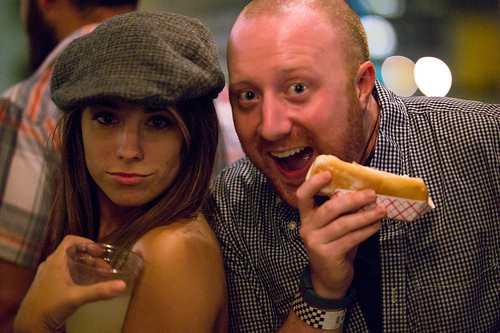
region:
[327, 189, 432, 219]
A small basket holding the hotdog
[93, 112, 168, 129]
The eyes of the woman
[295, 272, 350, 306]
The man is wearing a watch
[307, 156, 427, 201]
A hotdog in the basket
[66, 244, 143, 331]
A plastic cup full of a beverage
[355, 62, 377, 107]
The left ear of the man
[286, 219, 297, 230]
A button on the shirt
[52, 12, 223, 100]
The woman is wearing a hat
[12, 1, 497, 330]
A woman standing next to a man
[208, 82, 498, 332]
The man is wearing a dress shirt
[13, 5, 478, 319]
a man and woman smiling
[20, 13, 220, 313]
a woman holding a beverage in her hand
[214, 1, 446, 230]
a man holding a hotdog in his hand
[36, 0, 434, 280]
a man and woman leaning against each other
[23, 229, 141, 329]
a hand holding a beverage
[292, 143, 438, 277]
a hand holding a hotdog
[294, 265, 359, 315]
the band of a watch around a wrist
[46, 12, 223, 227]
a woman wearing a cap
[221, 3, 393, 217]
the head of a man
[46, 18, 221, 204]
the head of a woman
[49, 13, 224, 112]
the hat on the woman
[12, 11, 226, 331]
the woman wearing the hat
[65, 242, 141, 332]
the cup in the woman's hand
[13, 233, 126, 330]
the woman's hand holding the cup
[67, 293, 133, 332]
the liquid in the cup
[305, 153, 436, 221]
the food in the man's hand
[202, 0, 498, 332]
the man holding the food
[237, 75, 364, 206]
the hair on the man's face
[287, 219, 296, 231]
the button the man's shirt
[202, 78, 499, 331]
the shirt on the man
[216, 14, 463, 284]
man holding a hotdog sandwich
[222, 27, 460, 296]
man holding a hotdog sandwich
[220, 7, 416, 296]
man holding a hotdog sandwich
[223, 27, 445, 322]
man holding a hotdog sandwich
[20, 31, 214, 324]
girl holding a cup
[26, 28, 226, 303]
girl holding a cup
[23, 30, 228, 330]
girl holding a cup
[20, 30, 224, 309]
girl holding a cup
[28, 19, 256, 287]
girl holding a cup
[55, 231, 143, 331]
Woman holding a cup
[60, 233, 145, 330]
Woman is holding a cup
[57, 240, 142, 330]
Woman is holding a plastic cup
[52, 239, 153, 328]
Woman holding a clear cup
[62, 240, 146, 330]
Woman is holding a clear cup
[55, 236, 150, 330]
Woman holding a clear plastic cup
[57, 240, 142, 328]
Woman is holding a clear plastic cup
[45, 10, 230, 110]
Woman wearing a hat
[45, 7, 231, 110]
Woman is wearing a hat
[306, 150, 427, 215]
a large white hot dog bun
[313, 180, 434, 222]
a red and white container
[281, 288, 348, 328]
black and white bracelet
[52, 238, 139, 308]
glass in a woman's hand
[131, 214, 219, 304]
shoulder of a woman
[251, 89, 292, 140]
nose of a man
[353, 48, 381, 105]
ear of a man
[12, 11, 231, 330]
woman wearing gray hat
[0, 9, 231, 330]
woman holding half full glass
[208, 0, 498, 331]
smiling man holding hot dog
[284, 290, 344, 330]
an wearing black and white bracelet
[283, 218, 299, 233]
button in front of shirt